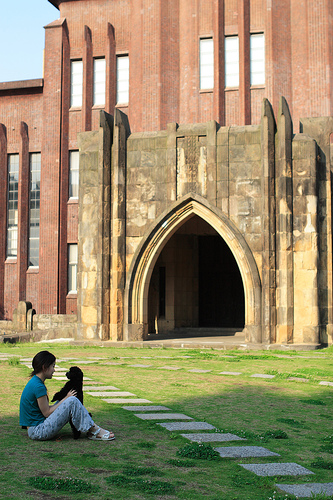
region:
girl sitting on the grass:
[12, 345, 137, 448]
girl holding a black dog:
[19, 346, 126, 445]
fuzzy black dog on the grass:
[49, 360, 98, 445]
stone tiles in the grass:
[43, 357, 317, 498]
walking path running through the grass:
[26, 349, 319, 498]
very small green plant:
[176, 437, 218, 464]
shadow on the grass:
[0, 394, 332, 499]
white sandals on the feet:
[84, 419, 114, 440]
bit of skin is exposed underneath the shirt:
[24, 426, 32, 430]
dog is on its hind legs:
[51, 364, 93, 443]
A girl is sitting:
[22, 351, 114, 441]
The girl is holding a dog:
[21, 351, 115, 440]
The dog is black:
[53, 366, 83, 439]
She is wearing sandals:
[87, 424, 115, 441]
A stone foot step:
[159, 420, 211, 432]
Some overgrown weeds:
[26, 473, 96, 494]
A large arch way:
[125, 194, 265, 342]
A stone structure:
[77, 110, 330, 345]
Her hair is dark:
[28, 350, 55, 373]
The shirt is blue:
[20, 376, 46, 425]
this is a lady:
[21, 351, 89, 453]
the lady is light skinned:
[40, 396, 47, 413]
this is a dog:
[66, 365, 80, 386]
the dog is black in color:
[69, 368, 80, 386]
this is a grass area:
[203, 370, 254, 423]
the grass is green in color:
[178, 468, 216, 495]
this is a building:
[87, 64, 324, 259]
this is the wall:
[131, 13, 189, 118]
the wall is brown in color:
[128, 9, 174, 110]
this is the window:
[226, 34, 241, 88]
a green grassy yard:
[6, 339, 327, 497]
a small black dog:
[51, 366, 83, 406]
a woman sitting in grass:
[16, 349, 113, 443]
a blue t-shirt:
[17, 374, 47, 428]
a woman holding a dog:
[16, 347, 117, 444]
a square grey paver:
[208, 442, 276, 457]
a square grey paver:
[237, 460, 313, 473]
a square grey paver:
[275, 482, 332, 496]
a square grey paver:
[180, 432, 245, 442]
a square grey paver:
[155, 418, 216, 429]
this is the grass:
[160, 385, 178, 395]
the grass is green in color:
[115, 469, 157, 493]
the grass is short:
[70, 454, 143, 486]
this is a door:
[132, 192, 266, 337]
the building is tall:
[8, 104, 327, 342]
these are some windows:
[7, 148, 39, 263]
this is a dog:
[56, 365, 79, 392]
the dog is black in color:
[68, 378, 79, 388]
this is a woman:
[14, 353, 115, 442]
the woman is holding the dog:
[26, 379, 84, 418]